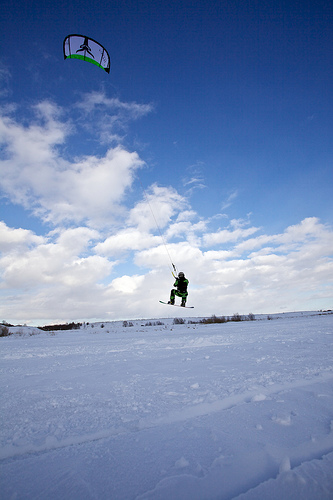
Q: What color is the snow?
A: White.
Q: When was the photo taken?
A: Winter.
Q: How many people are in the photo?
A: One.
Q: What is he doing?
A: Snowboarding.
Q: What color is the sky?
A: Blue.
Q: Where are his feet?
A: Snowboard.